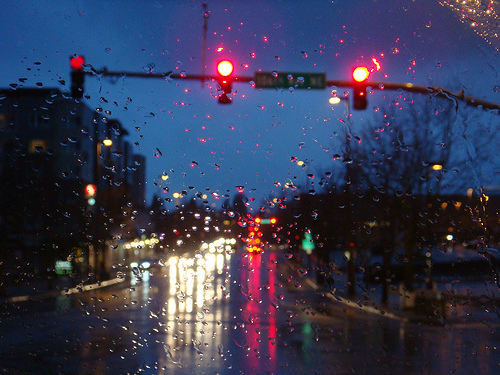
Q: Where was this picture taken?
A: On a street.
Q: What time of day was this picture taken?
A: Night time.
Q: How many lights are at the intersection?
A: Three.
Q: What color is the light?
A: Red.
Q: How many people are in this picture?
A: Zero.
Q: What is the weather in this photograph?
A: Raining.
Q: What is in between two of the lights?
A: A street sign.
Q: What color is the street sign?
A: Green.